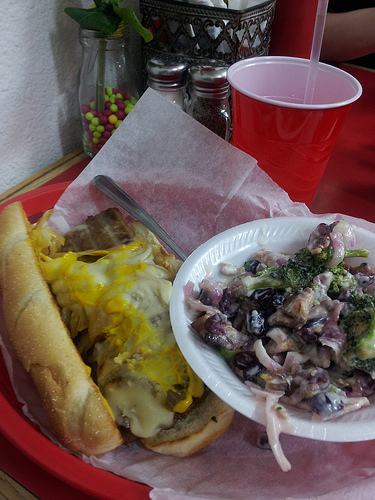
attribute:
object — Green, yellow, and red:
[107, 101, 118, 112]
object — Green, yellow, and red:
[104, 113, 117, 124]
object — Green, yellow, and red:
[96, 116, 109, 122]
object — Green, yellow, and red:
[105, 84, 114, 96]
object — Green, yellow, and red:
[83, 110, 96, 120]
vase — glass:
[73, 23, 149, 162]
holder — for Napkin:
[142, 7, 271, 59]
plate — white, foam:
[169, 215, 373, 442]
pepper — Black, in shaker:
[187, 59, 230, 143]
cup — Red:
[222, 40, 373, 115]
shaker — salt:
[140, 48, 190, 131]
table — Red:
[340, 105, 370, 194]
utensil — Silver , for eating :
[94, 173, 187, 271]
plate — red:
[2, 179, 374, 497]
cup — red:
[215, 53, 361, 221]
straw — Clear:
[302, 2, 329, 105]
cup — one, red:
[226, 53, 362, 207]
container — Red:
[221, 51, 365, 213]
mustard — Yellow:
[68, 257, 132, 306]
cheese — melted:
[121, 386, 146, 431]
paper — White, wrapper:
[97, 92, 238, 210]